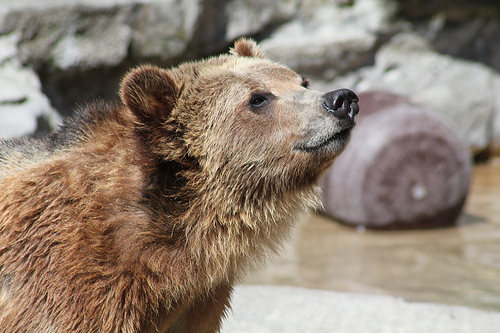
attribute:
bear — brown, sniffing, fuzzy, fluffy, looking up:
[1, 36, 360, 332]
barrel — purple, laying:
[311, 87, 474, 230]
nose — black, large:
[321, 88, 360, 120]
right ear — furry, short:
[120, 64, 181, 126]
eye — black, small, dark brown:
[252, 95, 267, 106]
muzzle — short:
[290, 87, 360, 160]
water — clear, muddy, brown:
[235, 153, 499, 311]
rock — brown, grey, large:
[258, 0, 415, 82]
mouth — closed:
[294, 122, 356, 151]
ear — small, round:
[230, 37, 266, 58]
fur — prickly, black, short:
[0, 37, 356, 332]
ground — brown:
[218, 283, 500, 332]